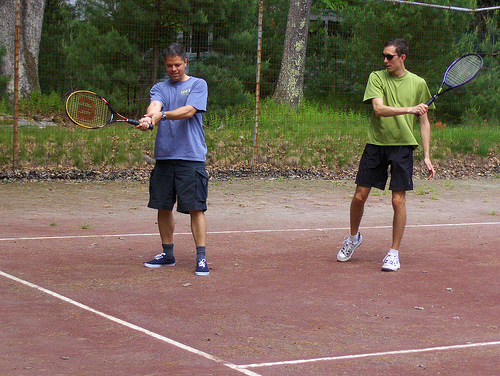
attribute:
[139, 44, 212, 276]
man — playing tennis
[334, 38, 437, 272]
man — playing tennis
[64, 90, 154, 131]
tennis racket — yellow, red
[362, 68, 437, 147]
t-shirt — green, short sleeved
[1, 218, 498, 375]
tennis court — red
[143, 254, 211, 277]
tennis shoes — blue, white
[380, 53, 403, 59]
sunglasses — black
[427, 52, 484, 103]
tennis racket — purple, blue, black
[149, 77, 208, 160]
shirt — blue, short sleeved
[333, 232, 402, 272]
sneakers — white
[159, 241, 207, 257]
socks — blue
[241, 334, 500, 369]
line — white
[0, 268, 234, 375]
line — white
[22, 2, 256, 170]
net — black, mesh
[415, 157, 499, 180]
leaves — brown